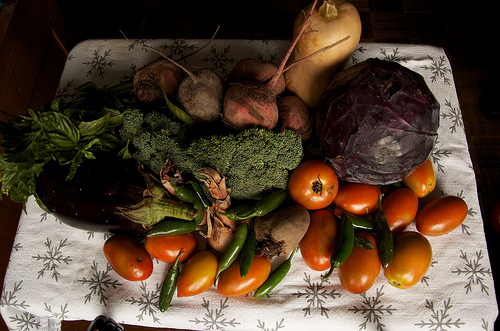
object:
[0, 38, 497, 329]
cloth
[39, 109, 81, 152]
basil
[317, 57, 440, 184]
cabbage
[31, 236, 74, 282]
snowflake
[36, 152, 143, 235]
bowl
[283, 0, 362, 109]
gourd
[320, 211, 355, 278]
pepper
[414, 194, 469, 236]
tomatoe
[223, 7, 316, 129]
beet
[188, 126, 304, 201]
broccoli